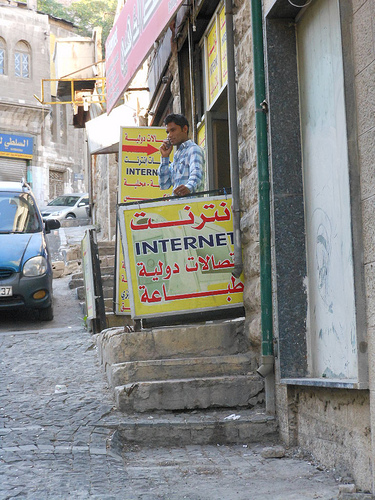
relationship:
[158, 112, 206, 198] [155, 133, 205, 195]
man in shirt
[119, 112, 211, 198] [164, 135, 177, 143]
man talking on phone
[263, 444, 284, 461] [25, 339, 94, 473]
brick on road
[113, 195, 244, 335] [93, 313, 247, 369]
sign on ground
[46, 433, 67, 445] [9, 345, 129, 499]
brick on road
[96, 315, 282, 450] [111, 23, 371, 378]
stairs by store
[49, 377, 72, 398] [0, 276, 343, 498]
brick on brick road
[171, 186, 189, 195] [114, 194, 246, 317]
hand on sign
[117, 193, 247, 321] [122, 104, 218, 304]
sign next to man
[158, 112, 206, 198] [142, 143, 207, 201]
man in shirt